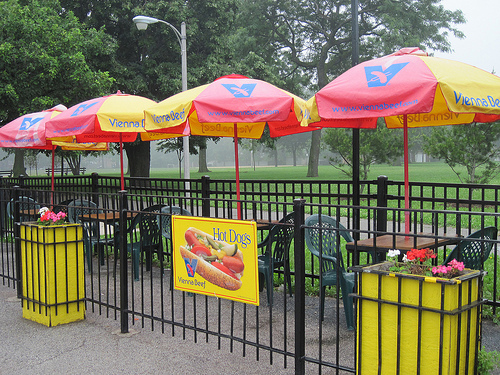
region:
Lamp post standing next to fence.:
[121, 8, 204, 235]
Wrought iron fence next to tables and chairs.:
[109, 190, 349, 374]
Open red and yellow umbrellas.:
[140, 44, 499, 151]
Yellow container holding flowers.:
[356, 243, 488, 374]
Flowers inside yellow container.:
[380, 243, 468, 282]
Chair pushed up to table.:
[302, 203, 363, 333]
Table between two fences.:
[81, 207, 142, 276]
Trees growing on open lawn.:
[3, 7, 163, 185]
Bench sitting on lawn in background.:
[38, 165, 93, 182]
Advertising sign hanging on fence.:
[155, 208, 272, 314]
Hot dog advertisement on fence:
[166, 210, 262, 308]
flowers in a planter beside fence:
[375, 244, 480, 285]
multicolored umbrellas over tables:
[0, 48, 498, 154]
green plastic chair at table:
[302, 207, 374, 322]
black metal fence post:
[112, 186, 137, 332]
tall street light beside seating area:
[132, 14, 202, 218]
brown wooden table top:
[350, 213, 455, 257]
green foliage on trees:
[8, 17, 106, 82]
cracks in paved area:
[25, 333, 138, 374]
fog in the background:
[154, 129, 339, 169]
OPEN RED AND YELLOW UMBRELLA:
[5, 111, 102, 150]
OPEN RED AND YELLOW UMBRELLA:
[53, 87, 163, 144]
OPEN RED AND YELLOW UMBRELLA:
[148, 67, 314, 138]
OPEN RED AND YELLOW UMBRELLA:
[317, 35, 496, 133]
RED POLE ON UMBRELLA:
[399, 119, 416, 225]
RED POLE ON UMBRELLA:
[227, 122, 247, 229]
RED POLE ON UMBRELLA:
[120, 145, 124, 199]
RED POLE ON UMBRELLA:
[46, 144, 58, 214]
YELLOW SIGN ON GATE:
[156, 216, 256, 310]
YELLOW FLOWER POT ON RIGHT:
[352, 249, 482, 359]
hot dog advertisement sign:
[169, 210, 261, 307]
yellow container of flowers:
[18, 204, 87, 326]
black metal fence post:
[287, 190, 305, 373]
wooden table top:
[79, 200, 140, 222]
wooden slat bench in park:
[45, 163, 87, 180]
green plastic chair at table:
[302, 208, 365, 325]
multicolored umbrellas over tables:
[2, 45, 498, 145]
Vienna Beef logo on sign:
[173, 253, 209, 290]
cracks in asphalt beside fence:
[9, 330, 108, 372]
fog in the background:
[212, 141, 317, 168]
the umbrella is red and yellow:
[317, 47, 497, 129]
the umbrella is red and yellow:
[161, 78, 311, 138]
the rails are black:
[272, 212, 334, 374]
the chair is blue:
[126, 204, 167, 279]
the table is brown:
[86, 199, 138, 221]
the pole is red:
[398, 124, 413, 239]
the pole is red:
[48, 153, 59, 218]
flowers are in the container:
[385, 240, 465, 280]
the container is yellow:
[356, 268, 462, 373]